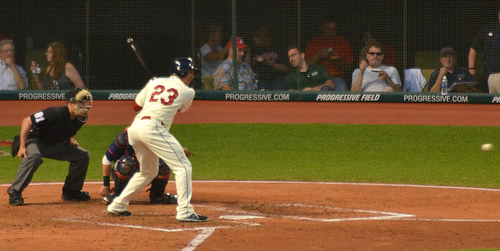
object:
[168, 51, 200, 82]
helmet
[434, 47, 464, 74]
face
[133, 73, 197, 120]
shirt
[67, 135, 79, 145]
hands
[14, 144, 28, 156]
hands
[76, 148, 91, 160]
knees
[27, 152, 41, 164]
knees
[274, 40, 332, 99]
man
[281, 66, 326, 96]
shirt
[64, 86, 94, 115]
safety mask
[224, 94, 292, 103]
advertising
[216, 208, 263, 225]
homeplate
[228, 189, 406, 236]
batter's box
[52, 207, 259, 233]
chalk outline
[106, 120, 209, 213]
catcher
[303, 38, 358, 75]
shirt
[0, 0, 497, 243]
field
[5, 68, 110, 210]
uniform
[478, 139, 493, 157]
ball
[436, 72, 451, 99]
water bottle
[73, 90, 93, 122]
mask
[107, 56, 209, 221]
batter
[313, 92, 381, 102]
word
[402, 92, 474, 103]
word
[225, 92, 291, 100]
word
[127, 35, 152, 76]
bat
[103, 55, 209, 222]
man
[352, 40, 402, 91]
man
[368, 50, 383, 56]
sunglasses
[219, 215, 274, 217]
surface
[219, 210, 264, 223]
plate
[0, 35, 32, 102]
man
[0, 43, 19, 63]
face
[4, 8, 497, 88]
fence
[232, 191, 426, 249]
lines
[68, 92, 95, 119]
face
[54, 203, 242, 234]
box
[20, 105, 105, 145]
shirt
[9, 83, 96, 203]
man